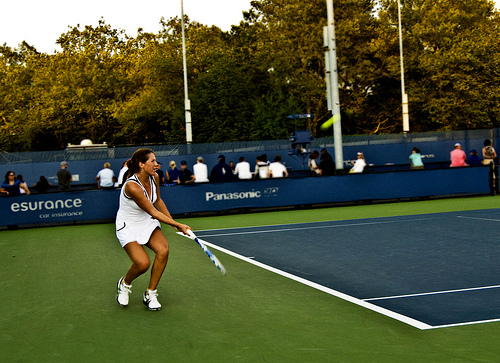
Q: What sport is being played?
A: Tennis.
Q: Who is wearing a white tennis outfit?
A: A woman.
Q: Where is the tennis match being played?
A: On a tennis court.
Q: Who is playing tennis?
A: A woman.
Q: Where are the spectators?
A: Behind the blue wall.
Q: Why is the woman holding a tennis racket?
A: She is playing tennis.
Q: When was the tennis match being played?
A: During daylight hours.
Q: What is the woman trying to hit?
A: A tennis ball.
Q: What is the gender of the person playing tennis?
A: Female.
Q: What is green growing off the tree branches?
A: Leaves.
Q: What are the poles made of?
A: Metal.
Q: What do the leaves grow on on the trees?
A: Branches.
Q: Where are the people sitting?
A: Behind the wall.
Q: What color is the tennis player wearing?
A: White and blue.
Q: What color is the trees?
A: Green.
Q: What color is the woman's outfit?
A: It is white and black.